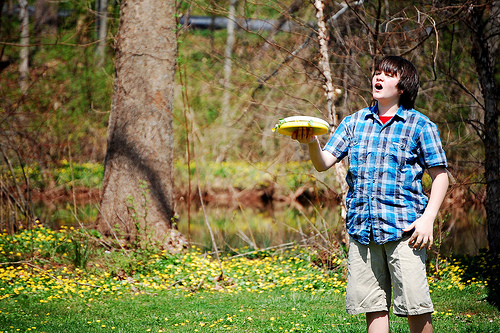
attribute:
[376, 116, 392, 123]
t-shirt — red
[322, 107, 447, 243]
blue shirt — under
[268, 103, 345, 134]
frsibee — yellow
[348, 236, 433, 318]
shorts — beige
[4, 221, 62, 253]
flowers — yellow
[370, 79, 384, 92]
mouth — open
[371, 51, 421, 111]
hair — long, brown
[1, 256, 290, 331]
grass/flowers — green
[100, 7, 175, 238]
tree trunk — large, brown